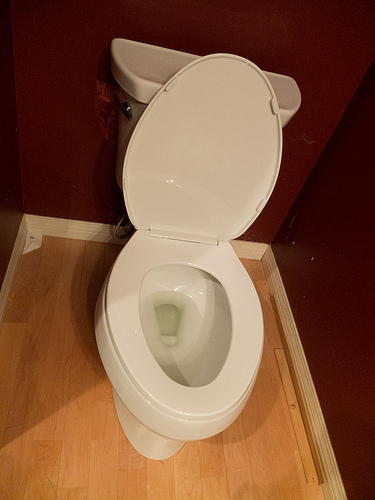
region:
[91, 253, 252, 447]
the toilet is clean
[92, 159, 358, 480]
the toilet is clean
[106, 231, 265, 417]
a white toilet seat.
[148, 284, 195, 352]
a drain in a toilet.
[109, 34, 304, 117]
the back of a white toilet tank.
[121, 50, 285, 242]
a toilet seat lid cover.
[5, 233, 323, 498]
a hardwood floor in a bathroom.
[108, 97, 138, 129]
toilet flush lever.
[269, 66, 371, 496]
the right wall of a bathroom.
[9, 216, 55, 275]
a piece of used tp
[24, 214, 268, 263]
white bathroom paneling.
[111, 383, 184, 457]
the bottom of a toilet.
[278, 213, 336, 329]
flaws on a red wall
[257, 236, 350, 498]
white trim on the wall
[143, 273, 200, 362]
still water in the toilet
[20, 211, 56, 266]
piece of paper in the corner of the wall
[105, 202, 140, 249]
silver toilet hose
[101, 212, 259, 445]
white toilet seat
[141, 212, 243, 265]
hinges on a toilet lid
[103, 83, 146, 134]
silver flushing handle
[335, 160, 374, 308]
red wall in the bathroom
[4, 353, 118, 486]
light colored hardwood floor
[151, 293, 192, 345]
Clear water in the toiliet.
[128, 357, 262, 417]
Front end of toliet seat.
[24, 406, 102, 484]
Finshed wood paneling floor.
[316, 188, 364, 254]
Reddish burgandy wall in bathroom.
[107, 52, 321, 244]
Back rest of toliet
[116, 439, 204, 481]
Bottom of toliet seat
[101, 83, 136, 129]
Silver toliet flush handle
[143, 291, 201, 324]
Clear low water level.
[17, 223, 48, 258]
White piece of paper in corner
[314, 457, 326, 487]
A piece of molding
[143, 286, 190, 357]
clear pooled toilet water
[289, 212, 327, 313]
white marks on a red wall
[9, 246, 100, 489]
light colored hard wood flooring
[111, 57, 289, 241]
white toilet lid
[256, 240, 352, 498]
white trim under a red wall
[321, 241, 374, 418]
dark red bathroom wall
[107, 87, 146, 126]
silver toilet handle to flush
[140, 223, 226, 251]
hinge of the toilet lid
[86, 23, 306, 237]
white porcelain toilet tank